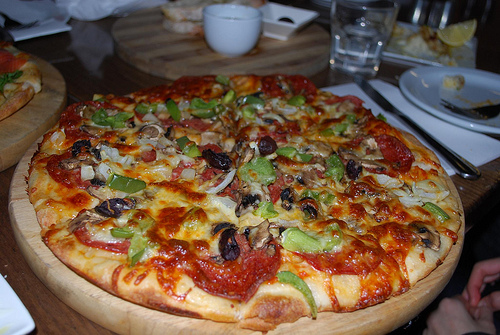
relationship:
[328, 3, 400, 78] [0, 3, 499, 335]
glass on table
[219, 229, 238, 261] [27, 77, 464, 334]
topping on pizza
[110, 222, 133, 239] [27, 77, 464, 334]
topping on pizza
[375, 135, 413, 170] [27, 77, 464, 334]
topping on pizza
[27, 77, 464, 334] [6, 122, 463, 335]
pizza on platform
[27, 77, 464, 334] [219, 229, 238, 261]
pizza with topping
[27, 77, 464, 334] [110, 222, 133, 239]
pizza with topping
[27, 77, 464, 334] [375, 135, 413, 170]
pizza with topping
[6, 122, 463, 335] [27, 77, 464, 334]
platform under pizza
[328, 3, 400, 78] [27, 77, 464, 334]
glass next to pizza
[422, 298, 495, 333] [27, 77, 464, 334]
hand near pizza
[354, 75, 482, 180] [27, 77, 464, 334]
knife next to pizza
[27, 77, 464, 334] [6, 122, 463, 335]
pizza on a platform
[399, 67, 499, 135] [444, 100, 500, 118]
plate with fork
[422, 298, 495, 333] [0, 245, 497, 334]
hand in bottom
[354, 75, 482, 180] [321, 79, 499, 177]
knife on napkin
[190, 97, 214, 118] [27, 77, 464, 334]
pepper on pizza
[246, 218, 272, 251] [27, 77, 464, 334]
mushroom on pizza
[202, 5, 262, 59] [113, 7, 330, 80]
bowl on plate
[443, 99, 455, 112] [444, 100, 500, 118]
tip of fork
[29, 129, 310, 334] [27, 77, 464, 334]
crust of pizza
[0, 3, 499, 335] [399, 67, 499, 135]
table with plate